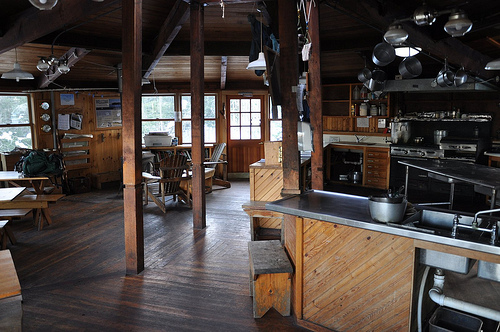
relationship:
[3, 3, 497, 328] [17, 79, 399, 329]
restaurant built of wood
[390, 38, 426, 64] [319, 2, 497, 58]
light fixture hanging from ceiling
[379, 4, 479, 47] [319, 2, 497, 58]
light fixture hanging from ceiling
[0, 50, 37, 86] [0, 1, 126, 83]
light fixture hanging from ceiling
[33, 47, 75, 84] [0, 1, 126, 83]
light fixture hanging from ceiling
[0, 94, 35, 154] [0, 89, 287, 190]
window on front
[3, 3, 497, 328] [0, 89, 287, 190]
restaurant has front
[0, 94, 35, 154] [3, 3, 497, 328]
window in restaurant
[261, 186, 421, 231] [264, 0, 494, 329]
countertop in kitchen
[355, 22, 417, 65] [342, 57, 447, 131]
pots with pans